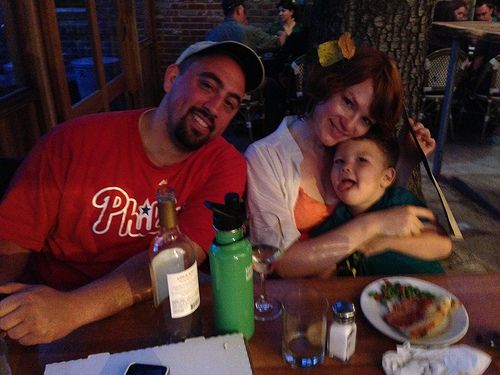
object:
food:
[367, 277, 459, 339]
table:
[0, 272, 499, 373]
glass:
[239, 207, 288, 327]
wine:
[248, 240, 285, 277]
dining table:
[0, 240, 500, 375]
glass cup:
[280, 289, 325, 370]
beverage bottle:
[201, 190, 256, 341]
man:
[0, 34, 272, 346]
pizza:
[368, 282, 454, 341]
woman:
[242, 44, 456, 279]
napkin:
[380, 343, 485, 375]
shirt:
[8, 102, 253, 284]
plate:
[360, 277, 469, 346]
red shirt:
[2, 107, 250, 292]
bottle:
[146, 175, 201, 342]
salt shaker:
[325, 298, 359, 362]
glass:
[276, 280, 333, 368]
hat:
[167, 41, 266, 96]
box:
[40, 329, 259, 375]